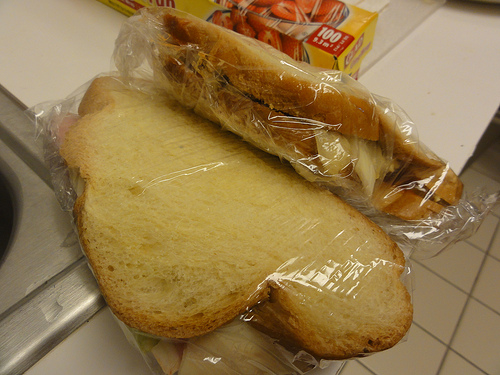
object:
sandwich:
[132, 2, 475, 224]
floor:
[418, 258, 500, 359]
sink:
[8, 156, 73, 336]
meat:
[311, 122, 351, 174]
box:
[105, 4, 378, 82]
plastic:
[266, 5, 308, 36]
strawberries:
[268, 41, 308, 54]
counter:
[408, 40, 492, 122]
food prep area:
[0, 0, 490, 362]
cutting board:
[383, 13, 414, 42]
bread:
[79, 78, 414, 359]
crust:
[152, 7, 463, 218]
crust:
[135, 313, 212, 335]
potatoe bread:
[60, 67, 412, 355]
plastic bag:
[130, 3, 474, 244]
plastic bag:
[51, 66, 401, 354]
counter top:
[14, 10, 99, 74]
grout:
[442, 342, 457, 352]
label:
[307, 22, 353, 57]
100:
[319, 26, 343, 42]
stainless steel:
[16, 246, 79, 323]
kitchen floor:
[375, 220, 499, 374]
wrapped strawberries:
[251, 23, 283, 45]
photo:
[224, 4, 333, 65]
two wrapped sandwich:
[34, 6, 460, 365]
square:
[395, 251, 472, 344]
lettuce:
[186, 51, 241, 96]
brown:
[244, 61, 273, 87]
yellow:
[159, 206, 238, 284]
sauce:
[390, 164, 436, 206]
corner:
[3, 136, 127, 331]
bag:
[174, 338, 280, 374]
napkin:
[235, 331, 270, 357]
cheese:
[356, 159, 380, 198]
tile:
[452, 290, 495, 375]